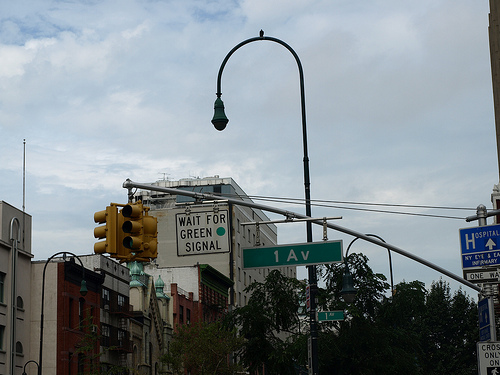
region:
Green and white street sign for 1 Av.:
[243, 232, 345, 264]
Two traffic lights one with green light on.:
[94, 198, 156, 269]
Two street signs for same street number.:
[241, 239, 346, 321]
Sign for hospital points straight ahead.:
[459, 226, 498, 266]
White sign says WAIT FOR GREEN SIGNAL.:
[177, 210, 229, 257]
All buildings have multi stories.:
[0, 177, 302, 372]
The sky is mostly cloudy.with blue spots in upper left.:
[4, 0, 499, 295]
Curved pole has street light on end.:
[211, 32, 318, 372]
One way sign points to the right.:
[461, 264, 498, 284]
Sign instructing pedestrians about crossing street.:
[474, 338, 499, 373]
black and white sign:
[174, 203, 222, 257]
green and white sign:
[247, 240, 338, 287]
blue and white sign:
[456, 218, 495, 276]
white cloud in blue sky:
[10, 19, 98, 88]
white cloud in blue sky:
[5, 69, 74, 117]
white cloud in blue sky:
[42, 131, 88, 176]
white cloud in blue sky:
[41, 186, 87, 236]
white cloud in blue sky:
[92, 21, 155, 110]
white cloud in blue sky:
[314, 19, 446, 90]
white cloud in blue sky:
[325, 106, 457, 176]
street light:
[212, 98, 232, 137]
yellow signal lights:
[93, 200, 166, 253]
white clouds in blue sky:
[7, 6, 86, 67]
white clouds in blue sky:
[9, 59, 70, 95]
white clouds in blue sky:
[46, 95, 82, 129]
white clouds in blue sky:
[63, 130, 110, 193]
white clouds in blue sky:
[26, 181, 81, 228]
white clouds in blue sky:
[79, 30, 126, 71]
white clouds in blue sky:
[131, 59, 189, 147]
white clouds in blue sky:
[339, 47, 431, 135]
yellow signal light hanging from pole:
[99, 202, 163, 261]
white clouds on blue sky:
[12, 12, 84, 56]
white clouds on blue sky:
[10, 58, 90, 108]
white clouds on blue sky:
[60, 119, 118, 165]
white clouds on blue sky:
[112, 32, 160, 87]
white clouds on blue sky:
[144, 122, 194, 161]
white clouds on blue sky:
[244, 83, 276, 152]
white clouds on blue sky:
[324, 74, 402, 165]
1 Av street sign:
[239, 239, 349, 269]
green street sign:
[237, 243, 351, 268]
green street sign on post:
[233, 232, 354, 272]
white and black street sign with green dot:
[170, 202, 237, 257]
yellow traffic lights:
[94, 182, 166, 273]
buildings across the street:
[4, 180, 238, 373]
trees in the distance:
[240, 251, 498, 368]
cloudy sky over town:
[0, 5, 497, 270]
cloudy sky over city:
[2, 10, 497, 283]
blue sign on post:
[455, 214, 498, 279]